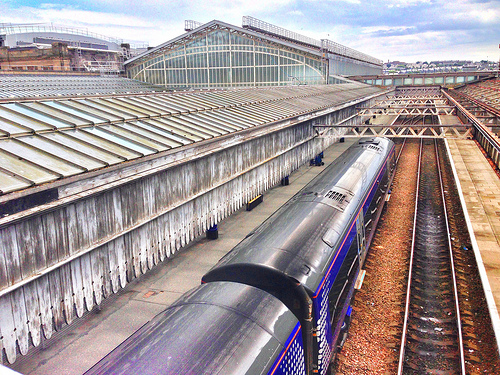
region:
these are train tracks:
[386, 118, 498, 373]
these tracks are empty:
[383, 134, 494, 370]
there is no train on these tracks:
[380, 136, 484, 370]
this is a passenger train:
[65, 126, 452, 371]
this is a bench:
[229, 165, 276, 222]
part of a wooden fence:
[3, 146, 260, 331]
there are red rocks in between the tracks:
[321, 172, 438, 371]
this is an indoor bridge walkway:
[350, 60, 497, 95]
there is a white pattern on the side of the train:
[307, 267, 343, 371]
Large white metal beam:
[306, 121, 478, 146]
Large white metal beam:
[349, 106, 463, 122]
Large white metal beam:
[371, 97, 449, 111]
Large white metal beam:
[20, 98, 75, 183]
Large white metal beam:
[55, 93, 137, 180]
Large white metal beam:
[100, 93, 195, 163]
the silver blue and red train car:
[63, 277, 303, 374]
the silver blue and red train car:
[205, 133, 405, 362]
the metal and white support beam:
[312, 120, 477, 141]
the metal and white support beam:
[356, 103, 461, 116]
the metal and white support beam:
[380, 96, 449, 105]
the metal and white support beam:
[393, 86, 440, 95]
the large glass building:
[128, 21, 386, 87]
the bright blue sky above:
[3, 3, 498, 75]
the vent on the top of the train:
[326, 187, 348, 201]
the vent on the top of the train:
[368, 143, 380, 150]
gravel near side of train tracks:
[372, 295, 385, 345]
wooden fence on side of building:
[60, 223, 143, 307]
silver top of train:
[278, 209, 315, 262]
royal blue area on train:
[333, 256, 355, 273]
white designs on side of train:
[313, 304, 339, 366]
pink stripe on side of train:
[330, 241, 357, 271]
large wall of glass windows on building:
[180, 46, 268, 87]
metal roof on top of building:
[24, 105, 96, 155]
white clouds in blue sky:
[338, 19, 431, 49]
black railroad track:
[412, 281, 447, 356]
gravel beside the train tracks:
[360, 312, 380, 372]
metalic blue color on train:
[321, 271, 346, 286]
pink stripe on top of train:
[332, 244, 353, 254]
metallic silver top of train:
[269, 226, 298, 258]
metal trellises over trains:
[343, 117, 475, 148]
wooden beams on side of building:
[37, 230, 158, 318]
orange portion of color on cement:
[129, 287, 159, 303]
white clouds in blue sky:
[374, 24, 440, 62]